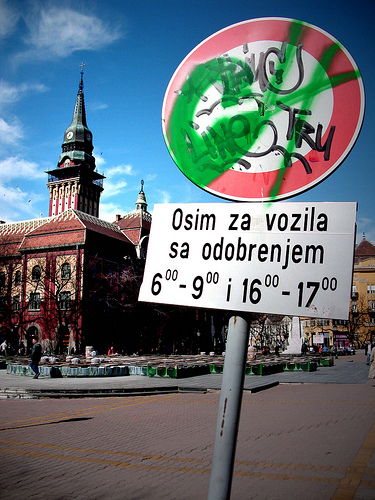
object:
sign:
[137, 200, 359, 322]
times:
[149, 267, 338, 309]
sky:
[0, 0, 375, 245]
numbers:
[150, 269, 339, 308]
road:
[0, 347, 375, 500]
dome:
[61, 61, 96, 155]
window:
[13, 268, 22, 288]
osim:
[172, 207, 216, 231]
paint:
[276, 100, 335, 161]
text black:
[174, 39, 337, 174]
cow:
[200, 316, 249, 500]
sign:
[156, 16, 364, 202]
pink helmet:
[141, 12, 179, 51]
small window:
[61, 262, 72, 280]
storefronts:
[299, 317, 375, 366]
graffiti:
[164, 16, 361, 211]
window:
[31, 263, 41, 282]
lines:
[4, 428, 375, 500]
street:
[0, 347, 375, 500]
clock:
[67, 131, 74, 140]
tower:
[42, 60, 108, 217]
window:
[28, 290, 43, 313]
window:
[366, 284, 375, 297]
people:
[29, 334, 43, 380]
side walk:
[0, 365, 295, 409]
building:
[283, 228, 374, 354]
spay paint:
[162, 19, 359, 208]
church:
[0, 60, 230, 359]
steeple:
[44, 55, 107, 214]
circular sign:
[161, 15, 367, 204]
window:
[60, 261, 72, 280]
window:
[56, 290, 72, 310]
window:
[12, 293, 20, 312]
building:
[0, 57, 150, 373]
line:
[0, 388, 181, 442]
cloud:
[0, 0, 170, 218]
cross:
[79, 61, 85, 71]